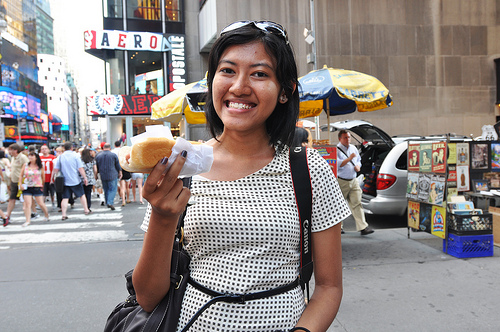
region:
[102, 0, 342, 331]
a woman is holding a hot dog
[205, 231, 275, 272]
pattern on the dress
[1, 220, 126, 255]
white stripes on road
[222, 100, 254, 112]
teeth of the woman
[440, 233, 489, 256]
the box is blue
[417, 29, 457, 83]
side of the wall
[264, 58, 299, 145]
hair of the woman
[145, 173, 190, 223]
hand of the woman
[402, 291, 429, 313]
the ground is concrete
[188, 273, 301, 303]
belt on the waist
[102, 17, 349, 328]
smiling woman holding a sandwich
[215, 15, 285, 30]
sunglasses on woman's head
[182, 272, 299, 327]
belt woman is wearing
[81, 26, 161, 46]
sign with big letters in blue and red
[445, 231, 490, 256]
blue carton on sidewalk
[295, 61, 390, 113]
blue and yellow umbrella right of the woman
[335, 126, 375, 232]
man in tan pants walking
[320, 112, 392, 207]
an open hatchback on a silver car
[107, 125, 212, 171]
the sandwich held by the woman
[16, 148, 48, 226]
woman in pink and white sleeveless top and shorts walking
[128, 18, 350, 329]
woman holding a hot dog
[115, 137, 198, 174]
hot dog in the woman's hand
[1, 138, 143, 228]
people crossing the street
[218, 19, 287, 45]
sunglasses on the woman's head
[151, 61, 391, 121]
black and yellow umbrellas behind the woman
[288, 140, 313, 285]
camera strap on the woman's shoulder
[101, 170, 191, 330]
black purse on the woman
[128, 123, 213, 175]
paper on the hot dog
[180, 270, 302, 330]
black belt on the woman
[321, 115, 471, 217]
car parked behind the woman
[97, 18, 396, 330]
this is a woman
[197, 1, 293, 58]
woman wearing glasses on head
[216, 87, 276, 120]
the woman is smiling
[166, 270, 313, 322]
woman wearing black belt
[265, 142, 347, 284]
woman with strap on her arm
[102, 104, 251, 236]
woman holding a hot dog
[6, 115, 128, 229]
people walking on the street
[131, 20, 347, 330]
A woman smiling at the camera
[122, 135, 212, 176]
Food in the woman's hand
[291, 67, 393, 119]
A yellow and blue umbrella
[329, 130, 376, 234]
A man walking on the sidewalk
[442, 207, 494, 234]
A black plastic crate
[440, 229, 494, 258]
A blue plastic crate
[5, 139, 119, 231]
People on the sidewalk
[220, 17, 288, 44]
Sunglasses on the woman's head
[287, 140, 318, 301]
A black camera strap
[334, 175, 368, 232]
Tan pants on the man